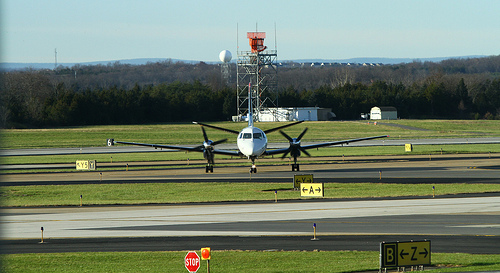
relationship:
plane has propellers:
[116, 99, 387, 173] [195, 126, 310, 161]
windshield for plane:
[238, 130, 280, 142] [80, 116, 421, 176]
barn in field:
[362, 104, 400, 121] [0, 117, 498, 271]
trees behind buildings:
[2, 62, 498, 120] [228, 95, 402, 126]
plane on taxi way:
[116, 99, 387, 173] [5, 151, 498, 178]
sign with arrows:
[299, 180, 325, 196] [300, 183, 322, 192]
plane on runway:
[105, 119, 388, 171] [2, 193, 497, 254]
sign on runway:
[374, 236, 434, 270] [8, 178, 483, 243]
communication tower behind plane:
[234, 22, 278, 123] [105, 119, 388, 171]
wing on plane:
[114, 142, 236, 163] [98, 110, 390, 175]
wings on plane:
[261, 133, 388, 157] [98, 110, 390, 175]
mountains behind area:
[1, 52, 498, 70] [238, 43, 397, 78]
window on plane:
[235, 128, 250, 145] [98, 110, 390, 175]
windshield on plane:
[251, 132, 263, 140] [98, 110, 390, 175]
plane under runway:
[100, 112, 394, 181] [2, 116, 497, 269]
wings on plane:
[106, 115, 408, 172] [97, 96, 388, 183]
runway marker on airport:
[33, 226, 53, 246] [0, 64, 495, 271]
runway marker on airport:
[309, 215, 324, 249] [0, 64, 495, 271]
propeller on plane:
[188, 125, 225, 163] [108, 82, 385, 172]